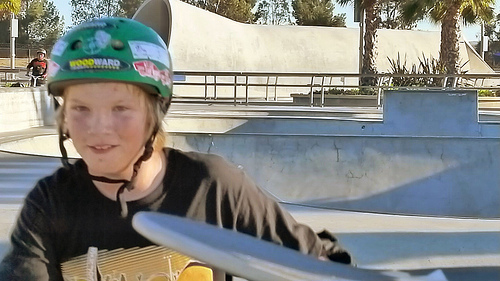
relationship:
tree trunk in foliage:
[338, 28, 401, 94] [311, 57, 484, 98]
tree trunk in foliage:
[338, 28, 401, 94] [335, 5, 486, 90]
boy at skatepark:
[7, 12, 353, 277] [130, 205, 346, 279]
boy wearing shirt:
[7, 12, 353, 277] [8, 145, 343, 280]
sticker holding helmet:
[64, 57, 129, 74] [39, 9, 178, 102]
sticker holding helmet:
[79, 29, 111, 55] [39, 9, 178, 102]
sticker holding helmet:
[124, 41, 174, 68] [39, 9, 178, 102]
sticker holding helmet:
[130, 63, 174, 85] [39, 9, 178, 102]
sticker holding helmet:
[43, 59, 60, 76] [39, 9, 178, 102]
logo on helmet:
[63, 56, 130, 71] [42, 16, 175, 100]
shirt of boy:
[8, 145, 343, 280] [7, 12, 353, 277]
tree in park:
[329, 0, 408, 92] [2, 3, 499, 277]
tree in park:
[390, 0, 499, 87] [2, 3, 499, 277]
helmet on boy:
[46, 17, 173, 217] [7, 12, 353, 277]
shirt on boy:
[8, 145, 343, 280] [7, 12, 353, 277]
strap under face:
[85, 171, 142, 196] [51, 82, 153, 181]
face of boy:
[51, 82, 153, 181] [7, 10, 262, 277]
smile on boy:
[82, 136, 122, 158] [13, 7, 418, 279]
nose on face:
[86, 105, 118, 142] [51, 82, 153, 181]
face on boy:
[51, 82, 153, 181] [7, 12, 353, 277]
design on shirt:
[74, 162, 494, 277] [8, 145, 343, 280]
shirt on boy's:
[8, 145, 343, 280] [17, 22, 217, 196]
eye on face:
[111, 102, 132, 112] [66, 83, 147, 173]